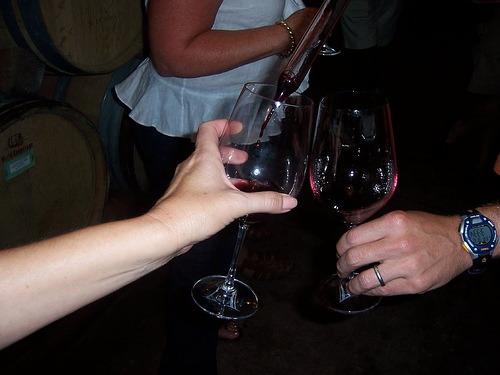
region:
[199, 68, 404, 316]
There are two wine glasses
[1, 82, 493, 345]
People are holding the wine glasses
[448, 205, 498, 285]
Blue and grey watch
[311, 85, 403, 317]
The wine glass has red wine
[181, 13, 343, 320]
Wine is being poured into the wine glass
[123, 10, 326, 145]
The person is wearing a white shirt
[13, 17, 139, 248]
The barrels are brown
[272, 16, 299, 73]
The bracelet is gold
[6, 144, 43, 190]
Green and white sticker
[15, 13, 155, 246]
The barrels are stacked on top of each other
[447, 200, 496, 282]
watch on his wrist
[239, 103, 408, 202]
two wine glasses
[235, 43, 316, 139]
wine being poured in to glasses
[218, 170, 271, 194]
wine in the glass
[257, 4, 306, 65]
woman wearing a bracelet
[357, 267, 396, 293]
man wearing a wedding band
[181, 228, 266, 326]
stem of the wine glass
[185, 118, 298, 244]
woman holding a wine glass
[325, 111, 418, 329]
man holding a wine glass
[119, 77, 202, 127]
woman has ruffles on the bottom of her top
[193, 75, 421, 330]
Two wine glasses in people hands.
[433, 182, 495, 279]
The person is wearing a watch.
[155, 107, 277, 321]
The person is holding a wine glass.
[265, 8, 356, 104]
Someone is pouring wine in the glass.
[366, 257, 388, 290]
The person is wearing a ring.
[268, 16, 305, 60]
A lady wearing a bracelet.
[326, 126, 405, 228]
Red wine is in the glass.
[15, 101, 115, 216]
Barrel on the floor.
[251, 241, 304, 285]
The person is wearing brown shoes.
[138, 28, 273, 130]
The lady is wearing a white shirt.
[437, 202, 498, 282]
Blue, silver, and yellow watch.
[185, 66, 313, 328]
Clear wine glass in hand.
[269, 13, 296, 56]
Gold beaded bracelet on wrist.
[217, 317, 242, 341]
Painted toe nails on foot.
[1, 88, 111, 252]
Wood barrel in background.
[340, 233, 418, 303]
Silver ring on the finger.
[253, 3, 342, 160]
Wine being poured into glass.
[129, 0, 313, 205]
White shirt on woman.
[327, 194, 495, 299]
Left hand holding glass.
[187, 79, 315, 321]
a clear wine glass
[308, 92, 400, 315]
a stemmed wine glass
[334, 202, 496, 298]
a man's hand wiht wedding ring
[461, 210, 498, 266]
a watch with blue around the face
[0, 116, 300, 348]
a woman's hand and forearm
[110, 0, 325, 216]
the lower half of a woman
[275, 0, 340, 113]
a bottle pouring a liquid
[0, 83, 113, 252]
a wooden barrel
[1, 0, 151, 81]
a brown wooden barrel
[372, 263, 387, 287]
a wedding ring